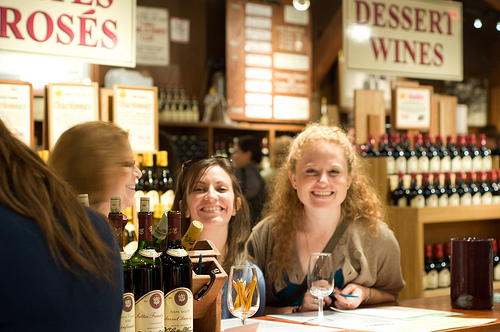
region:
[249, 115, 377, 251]
this is a woman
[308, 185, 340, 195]
the woman is smiling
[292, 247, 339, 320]
this is a glass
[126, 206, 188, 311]
these are bottles of wines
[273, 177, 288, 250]
the hair is long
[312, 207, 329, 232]
the woman is light skinned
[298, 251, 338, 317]
the glass is empty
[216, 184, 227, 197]
the eye is open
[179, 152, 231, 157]
this is a goggles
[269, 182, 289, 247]
the hair is pale brown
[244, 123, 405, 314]
A smiling blond woman.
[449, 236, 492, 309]
A brown ceramic vessel.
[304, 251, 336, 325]
An empty wine glass.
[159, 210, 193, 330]
An opened bottle of wine.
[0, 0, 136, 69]
A sign with red lettering.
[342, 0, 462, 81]
A sign with "DESSERT WINES" in red letters.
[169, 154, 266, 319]
A smiling brunette woman with sunglasses on top of her head.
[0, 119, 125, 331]
A woman turned away from the camera.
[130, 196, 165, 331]
A wine bottle with a partially attached cork.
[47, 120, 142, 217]
A smiling woman with glasses.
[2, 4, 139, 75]
Advertisement for a kind of wine.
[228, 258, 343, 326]
Wine glasses on the counter.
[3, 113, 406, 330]
Women enjoying wine.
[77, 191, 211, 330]
Wine bottles with corks.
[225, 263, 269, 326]
Wine glass with pencils.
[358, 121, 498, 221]
Wine bottles with red tops.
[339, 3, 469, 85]
Sign for dessert wines in the background.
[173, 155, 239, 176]
Glasses on top of girl's head.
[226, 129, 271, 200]
Person standing in the background.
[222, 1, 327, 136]
Chart in the background.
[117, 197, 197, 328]
these are champagne bottles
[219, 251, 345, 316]
these are champagne glasses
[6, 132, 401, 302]
these are several women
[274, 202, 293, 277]
the hair is long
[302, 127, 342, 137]
the hair is long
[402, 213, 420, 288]
this is a shelf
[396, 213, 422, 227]
the shelf is wooden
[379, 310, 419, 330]
this is a paper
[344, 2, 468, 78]
this is a signboard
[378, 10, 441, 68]
the writings are in bold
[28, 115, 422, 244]
Happy wine drinkers.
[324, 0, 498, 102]
The Dessert Wine area.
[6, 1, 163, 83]
The Roses Wine area.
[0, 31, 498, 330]
An entire store devoted to wines.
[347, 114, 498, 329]
Many wines are stacked and on display.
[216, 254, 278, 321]
Small pencils in a wine glass.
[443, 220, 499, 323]
A large vessel on the countertop.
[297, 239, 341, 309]
An empty glass of wine.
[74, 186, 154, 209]
Three corks in a row.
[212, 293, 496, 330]
Forms to fill out about their experience with the wines.